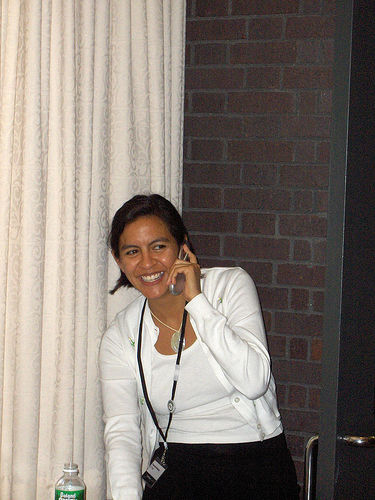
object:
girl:
[99, 193, 300, 500]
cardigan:
[100, 267, 285, 500]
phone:
[168, 239, 190, 296]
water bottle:
[53, 463, 87, 499]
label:
[55, 490, 85, 500]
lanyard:
[135, 297, 188, 440]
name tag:
[141, 459, 165, 488]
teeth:
[140, 272, 163, 283]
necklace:
[148, 309, 186, 354]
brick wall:
[181, 0, 333, 500]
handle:
[303, 434, 320, 500]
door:
[316, 0, 375, 500]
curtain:
[0, 0, 187, 499]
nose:
[139, 251, 157, 270]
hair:
[106, 193, 199, 298]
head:
[109, 193, 185, 300]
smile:
[138, 270, 165, 287]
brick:
[193, 45, 228, 65]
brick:
[318, 91, 331, 114]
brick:
[277, 214, 328, 239]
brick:
[280, 163, 330, 192]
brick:
[227, 141, 293, 166]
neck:
[147, 289, 192, 309]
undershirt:
[151, 339, 282, 443]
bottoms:
[142, 431, 299, 500]